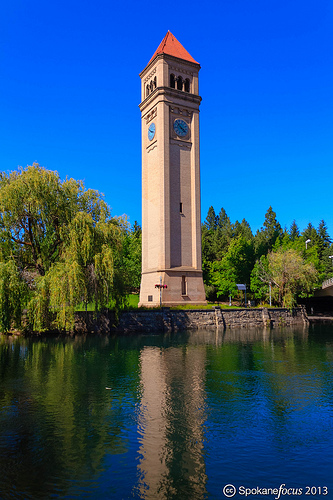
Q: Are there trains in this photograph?
A: No, there are no trains.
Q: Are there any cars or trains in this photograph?
A: No, there are no trains or cars.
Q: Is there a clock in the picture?
A: Yes, there is a clock.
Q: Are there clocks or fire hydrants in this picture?
A: Yes, there is a clock.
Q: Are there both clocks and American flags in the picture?
A: No, there is a clock but no American flags.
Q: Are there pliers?
A: No, there are no pliers.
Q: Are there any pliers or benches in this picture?
A: No, there are no pliers or benches.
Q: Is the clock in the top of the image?
A: Yes, the clock is in the top of the image.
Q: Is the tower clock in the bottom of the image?
A: No, the clock is in the top of the image.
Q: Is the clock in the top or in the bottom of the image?
A: The clock is in the top of the image.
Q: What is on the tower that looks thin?
A: The clock is on the tower.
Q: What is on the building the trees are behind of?
A: The clock is on the tower.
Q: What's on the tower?
A: The clock is on the tower.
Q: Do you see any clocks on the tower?
A: Yes, there is a clock on the tower.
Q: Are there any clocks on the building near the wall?
A: Yes, there is a clock on the tower.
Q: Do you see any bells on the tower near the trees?
A: No, there is a clock on the tower.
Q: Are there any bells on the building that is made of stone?
A: No, there is a clock on the tower.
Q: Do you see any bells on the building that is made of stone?
A: No, there is a clock on the tower.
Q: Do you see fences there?
A: No, there are no fences.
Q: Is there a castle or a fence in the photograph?
A: No, there are no fences or castles.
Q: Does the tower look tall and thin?
A: Yes, the tower is tall and thin.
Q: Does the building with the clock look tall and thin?
A: Yes, the tower is tall and thin.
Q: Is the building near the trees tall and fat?
A: No, the tower is tall but thin.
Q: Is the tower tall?
A: Yes, the tower is tall.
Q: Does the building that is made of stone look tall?
A: Yes, the tower is tall.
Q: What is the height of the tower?
A: The tower is tall.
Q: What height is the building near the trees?
A: The tower is tall.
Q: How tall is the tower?
A: The tower is tall.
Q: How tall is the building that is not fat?
A: The tower is tall.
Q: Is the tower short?
A: No, the tower is tall.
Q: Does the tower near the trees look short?
A: No, the tower is tall.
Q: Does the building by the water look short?
A: No, the tower is tall.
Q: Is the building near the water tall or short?
A: The tower is tall.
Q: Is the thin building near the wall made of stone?
A: Yes, the tower is made of stone.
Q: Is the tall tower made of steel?
A: No, the tower is made of stone.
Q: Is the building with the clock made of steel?
A: No, the tower is made of stone.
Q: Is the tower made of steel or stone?
A: The tower is made of stone.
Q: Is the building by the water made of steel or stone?
A: The tower is made of stone.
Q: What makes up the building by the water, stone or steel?
A: The tower is made of stone.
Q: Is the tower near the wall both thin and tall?
A: Yes, the tower is thin and tall.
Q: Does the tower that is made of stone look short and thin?
A: No, the tower is thin but tall.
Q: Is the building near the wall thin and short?
A: No, the tower is thin but tall.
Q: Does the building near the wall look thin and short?
A: No, the tower is thin but tall.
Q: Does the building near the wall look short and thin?
A: No, the tower is thin but tall.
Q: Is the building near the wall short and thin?
A: No, the tower is thin but tall.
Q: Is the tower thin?
A: Yes, the tower is thin.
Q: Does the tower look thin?
A: Yes, the tower is thin.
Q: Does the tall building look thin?
A: Yes, the tower is thin.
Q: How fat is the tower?
A: The tower is thin.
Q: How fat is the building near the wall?
A: The tower is thin.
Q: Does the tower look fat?
A: No, the tower is thin.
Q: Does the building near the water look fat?
A: No, the tower is thin.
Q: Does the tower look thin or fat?
A: The tower is thin.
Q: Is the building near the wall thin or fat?
A: The tower is thin.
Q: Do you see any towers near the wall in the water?
A: Yes, there is a tower near the wall.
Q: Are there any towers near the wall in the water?
A: Yes, there is a tower near the wall.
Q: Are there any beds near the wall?
A: No, there is a tower near the wall.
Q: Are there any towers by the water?
A: Yes, there is a tower by the water.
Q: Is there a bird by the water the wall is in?
A: No, there is a tower by the water.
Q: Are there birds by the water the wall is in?
A: No, there is a tower by the water.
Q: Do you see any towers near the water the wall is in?
A: Yes, there is a tower near the water.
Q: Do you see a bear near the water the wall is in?
A: No, there is a tower near the water.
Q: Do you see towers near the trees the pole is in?
A: Yes, there is a tower near the trees.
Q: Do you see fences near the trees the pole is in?
A: No, there is a tower near the trees.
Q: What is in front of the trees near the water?
A: The tower is in front of the trees.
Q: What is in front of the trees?
A: The tower is in front of the trees.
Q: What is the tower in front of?
A: The tower is in front of the trees.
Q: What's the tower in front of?
A: The tower is in front of the trees.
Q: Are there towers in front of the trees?
A: Yes, there is a tower in front of the trees.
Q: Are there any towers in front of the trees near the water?
A: Yes, there is a tower in front of the trees.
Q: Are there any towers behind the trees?
A: No, the tower is in front of the trees.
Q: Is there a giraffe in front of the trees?
A: No, there is a tower in front of the trees.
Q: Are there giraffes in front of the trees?
A: No, there is a tower in front of the trees.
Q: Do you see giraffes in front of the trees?
A: No, there is a tower in front of the trees.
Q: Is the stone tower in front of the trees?
A: Yes, the tower is in front of the trees.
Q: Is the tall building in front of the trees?
A: Yes, the tower is in front of the trees.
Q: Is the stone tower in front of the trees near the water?
A: Yes, the tower is in front of the trees.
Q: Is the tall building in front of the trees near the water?
A: Yes, the tower is in front of the trees.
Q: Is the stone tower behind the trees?
A: No, the tower is in front of the trees.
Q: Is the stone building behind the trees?
A: No, the tower is in front of the trees.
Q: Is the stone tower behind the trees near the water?
A: No, the tower is in front of the trees.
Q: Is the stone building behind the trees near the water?
A: No, the tower is in front of the trees.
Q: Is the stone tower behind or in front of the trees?
A: The tower is in front of the trees.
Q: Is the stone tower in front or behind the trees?
A: The tower is in front of the trees.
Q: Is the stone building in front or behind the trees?
A: The tower is in front of the trees.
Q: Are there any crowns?
A: No, there are no crowns.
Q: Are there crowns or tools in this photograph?
A: No, there are no crowns or tools.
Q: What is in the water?
A: The wall is in the water.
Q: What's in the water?
A: The wall is in the water.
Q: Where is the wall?
A: The wall is in the water.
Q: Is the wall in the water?
A: Yes, the wall is in the water.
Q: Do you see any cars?
A: No, there are no cars.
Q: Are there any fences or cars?
A: No, there are no cars or fences.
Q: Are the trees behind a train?
A: No, the trees are behind the tower.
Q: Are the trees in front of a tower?
A: No, the trees are behind a tower.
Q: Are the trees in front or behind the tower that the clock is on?
A: The trees are behind the tower.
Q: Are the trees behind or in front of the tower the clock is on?
A: The trees are behind the tower.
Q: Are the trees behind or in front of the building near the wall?
A: The trees are behind the tower.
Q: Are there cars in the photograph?
A: No, there are no cars.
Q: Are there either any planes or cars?
A: No, there are no cars or planes.